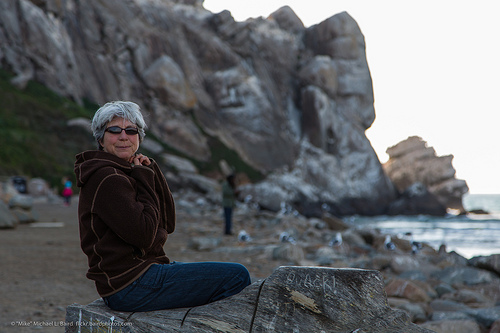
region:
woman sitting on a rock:
[69, 95, 253, 314]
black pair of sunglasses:
[101, 121, 141, 138]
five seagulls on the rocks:
[229, 226, 424, 258]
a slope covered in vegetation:
[1, 54, 268, 206]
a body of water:
[331, 191, 498, 263]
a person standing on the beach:
[219, 171, 243, 238]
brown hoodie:
[67, 145, 179, 302]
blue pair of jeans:
[99, 258, 252, 315]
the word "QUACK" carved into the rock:
[282, 268, 338, 296]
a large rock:
[60, 264, 439, 331]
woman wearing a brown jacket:
[67, 96, 262, 312]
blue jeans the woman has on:
[143, 275, 198, 302]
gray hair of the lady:
[85, 98, 145, 123]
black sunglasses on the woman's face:
[105, 122, 143, 138]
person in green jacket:
[214, 166, 241, 233]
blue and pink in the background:
[62, 170, 72, 210]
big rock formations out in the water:
[368, 127, 473, 214]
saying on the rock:
[281, 264, 343, 296]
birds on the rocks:
[241, 227, 433, 253]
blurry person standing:
[8, 170, 29, 200]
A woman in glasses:
[86, 102, 156, 163]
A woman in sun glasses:
[90, 103, 142, 158]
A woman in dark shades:
[87, 93, 144, 159]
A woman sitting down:
[72, 85, 259, 301]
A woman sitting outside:
[57, 98, 261, 303]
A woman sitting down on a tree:
[65, 94, 245, 296]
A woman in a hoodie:
[62, 94, 239, 299]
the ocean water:
[355, 218, 480, 251]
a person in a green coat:
[215, 169, 235, 237]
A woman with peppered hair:
[93, 101, 156, 152]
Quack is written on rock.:
[277, 265, 353, 298]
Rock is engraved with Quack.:
[272, 268, 372, 312]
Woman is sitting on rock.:
[57, 87, 407, 326]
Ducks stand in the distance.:
[238, 203, 453, 264]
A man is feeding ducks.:
[209, 163, 454, 260]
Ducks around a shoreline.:
[324, 190, 498, 261]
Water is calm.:
[346, 214, 498, 264]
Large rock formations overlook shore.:
[8, 6, 381, 201]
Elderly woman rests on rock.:
[70, 94, 401, 328]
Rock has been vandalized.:
[252, 263, 402, 328]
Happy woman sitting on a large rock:
[72, 100, 250, 316]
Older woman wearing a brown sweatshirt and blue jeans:
[71, 98, 253, 314]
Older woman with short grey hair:
[72, 97, 251, 316]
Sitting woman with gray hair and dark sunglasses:
[70, 98, 250, 315]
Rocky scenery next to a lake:
[0, 0, 495, 332]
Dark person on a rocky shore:
[220, 170, 246, 237]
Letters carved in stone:
[282, 267, 339, 297]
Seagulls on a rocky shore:
[234, 226, 419, 253]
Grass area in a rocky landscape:
[0, 56, 261, 205]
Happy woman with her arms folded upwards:
[72, 98, 250, 313]